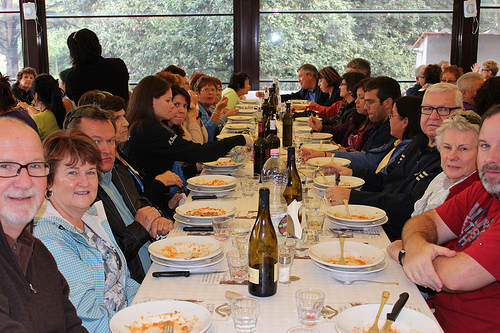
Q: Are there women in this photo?
A: Yes, there is a woman.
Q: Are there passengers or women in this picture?
A: Yes, there is a woman.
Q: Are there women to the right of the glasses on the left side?
A: Yes, there is a woman to the right of the glasses.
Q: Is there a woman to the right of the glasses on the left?
A: Yes, there is a woman to the right of the glasses.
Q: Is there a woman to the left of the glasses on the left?
A: No, the woman is to the right of the glasses.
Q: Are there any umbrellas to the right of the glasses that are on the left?
A: No, there is a woman to the right of the glasses.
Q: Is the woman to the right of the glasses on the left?
A: Yes, the woman is to the right of the glasses.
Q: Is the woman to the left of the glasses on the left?
A: No, the woman is to the right of the glasses.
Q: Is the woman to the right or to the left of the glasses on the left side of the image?
A: The woman is to the right of the glasses.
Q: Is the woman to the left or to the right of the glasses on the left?
A: The woman is to the right of the glasses.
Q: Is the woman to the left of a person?
A: Yes, the woman is to the left of a person.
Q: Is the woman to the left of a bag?
A: No, the woman is to the left of a person.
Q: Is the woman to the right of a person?
A: Yes, the woman is to the right of a person.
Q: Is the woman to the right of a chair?
A: No, the woman is to the right of a person.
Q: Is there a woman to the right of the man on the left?
A: Yes, there is a woman to the right of the man.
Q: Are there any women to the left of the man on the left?
A: No, the woman is to the right of the man.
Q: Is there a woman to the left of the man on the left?
A: No, the woman is to the right of the man.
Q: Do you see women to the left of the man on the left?
A: No, the woman is to the right of the man.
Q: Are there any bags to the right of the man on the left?
A: No, there is a woman to the right of the man.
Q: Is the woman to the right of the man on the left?
A: Yes, the woman is to the right of the man.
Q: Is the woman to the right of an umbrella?
A: No, the woman is to the right of the man.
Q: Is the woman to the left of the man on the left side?
A: No, the woman is to the right of the man.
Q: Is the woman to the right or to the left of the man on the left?
A: The woman is to the right of the man.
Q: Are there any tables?
A: Yes, there is a table.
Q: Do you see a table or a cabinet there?
A: Yes, there is a table.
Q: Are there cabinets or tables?
A: Yes, there is a table.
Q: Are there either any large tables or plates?
A: Yes, there is a large table.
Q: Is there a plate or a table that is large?
A: Yes, the table is large.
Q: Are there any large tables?
A: Yes, there is a large table.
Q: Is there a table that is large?
A: Yes, there is a table that is large.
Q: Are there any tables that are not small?
A: Yes, there is a large table.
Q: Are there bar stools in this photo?
A: No, there are no bar stools.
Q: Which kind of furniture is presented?
A: The furniture is a table.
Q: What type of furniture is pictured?
A: The furniture is a table.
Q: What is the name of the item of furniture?
A: The piece of furniture is a table.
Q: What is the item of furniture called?
A: The piece of furniture is a table.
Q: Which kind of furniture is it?
A: The piece of furniture is a table.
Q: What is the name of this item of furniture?
A: This is a table.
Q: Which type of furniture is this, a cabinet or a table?
A: This is a table.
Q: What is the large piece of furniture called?
A: The piece of furniture is a table.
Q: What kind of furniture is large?
A: The furniture is a table.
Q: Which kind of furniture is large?
A: The furniture is a table.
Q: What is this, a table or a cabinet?
A: This is a table.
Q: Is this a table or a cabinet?
A: This is a table.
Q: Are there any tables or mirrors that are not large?
A: No, there is a table but it is large.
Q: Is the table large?
A: Yes, the table is large.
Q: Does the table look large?
A: Yes, the table is large.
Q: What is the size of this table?
A: The table is large.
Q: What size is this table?
A: The table is large.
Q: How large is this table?
A: The table is large.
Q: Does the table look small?
A: No, the table is large.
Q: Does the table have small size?
A: No, the table is large.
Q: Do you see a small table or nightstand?
A: No, there is a table but it is large.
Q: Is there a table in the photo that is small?
A: No, there is a table but it is large.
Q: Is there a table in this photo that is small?
A: No, there is a table but it is large.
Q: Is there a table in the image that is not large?
A: No, there is a table but it is large.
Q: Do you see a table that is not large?
A: No, there is a table but it is large.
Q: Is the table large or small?
A: The table is large.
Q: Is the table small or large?
A: The table is large.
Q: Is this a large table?
A: Yes, this is a large table.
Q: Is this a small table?
A: No, this is a large table.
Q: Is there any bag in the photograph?
A: No, there are no bags.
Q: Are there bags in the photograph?
A: No, there are no bags.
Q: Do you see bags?
A: No, there are no bags.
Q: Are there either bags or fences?
A: No, there are no bags or fences.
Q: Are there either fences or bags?
A: No, there are no bags or fences.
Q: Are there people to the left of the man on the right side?
A: Yes, there is a person to the left of the man.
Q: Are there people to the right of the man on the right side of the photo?
A: No, the person is to the left of the man.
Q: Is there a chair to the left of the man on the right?
A: No, there is a person to the left of the man.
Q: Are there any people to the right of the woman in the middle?
A: Yes, there is a person to the right of the woman.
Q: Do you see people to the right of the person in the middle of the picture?
A: Yes, there is a person to the right of the woman.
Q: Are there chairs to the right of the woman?
A: No, there is a person to the right of the woman.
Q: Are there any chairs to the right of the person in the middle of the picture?
A: No, there is a person to the right of the woman.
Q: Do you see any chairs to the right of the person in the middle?
A: No, there is a person to the right of the woman.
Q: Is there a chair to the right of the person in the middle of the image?
A: No, there is a person to the right of the woman.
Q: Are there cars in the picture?
A: No, there are no cars.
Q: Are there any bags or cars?
A: No, there are no cars or bags.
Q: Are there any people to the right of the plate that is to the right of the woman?
A: Yes, there is a person to the right of the plate.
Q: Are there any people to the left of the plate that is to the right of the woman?
A: No, the person is to the right of the plate.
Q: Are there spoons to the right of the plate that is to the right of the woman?
A: No, there is a person to the right of the plate.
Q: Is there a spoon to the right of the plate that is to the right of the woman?
A: No, there is a person to the right of the plate.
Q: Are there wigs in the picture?
A: No, there are no wigs.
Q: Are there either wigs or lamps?
A: No, there are no wigs or lamps.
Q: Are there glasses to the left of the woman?
A: Yes, there are glasses to the left of the woman.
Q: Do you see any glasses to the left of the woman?
A: Yes, there are glasses to the left of the woman.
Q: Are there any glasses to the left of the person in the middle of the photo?
A: Yes, there are glasses to the left of the woman.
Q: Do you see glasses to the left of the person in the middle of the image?
A: Yes, there are glasses to the left of the woman.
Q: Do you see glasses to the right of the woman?
A: No, the glasses are to the left of the woman.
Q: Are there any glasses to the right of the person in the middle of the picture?
A: No, the glasses are to the left of the woman.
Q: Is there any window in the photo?
A: Yes, there are windows.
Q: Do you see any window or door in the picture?
A: Yes, there are windows.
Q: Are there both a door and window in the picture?
A: No, there are windows but no doors.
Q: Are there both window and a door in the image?
A: No, there are windows but no doors.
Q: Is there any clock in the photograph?
A: No, there are no clocks.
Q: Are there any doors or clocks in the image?
A: No, there are no clocks or doors.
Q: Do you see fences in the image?
A: No, there are no fences.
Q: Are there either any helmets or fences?
A: No, there are no fences or helmets.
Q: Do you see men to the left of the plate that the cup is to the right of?
A: Yes, there is a man to the left of the plate.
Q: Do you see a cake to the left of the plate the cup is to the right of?
A: No, there is a man to the left of the plate.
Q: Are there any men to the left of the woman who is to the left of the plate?
A: Yes, there is a man to the left of the woman.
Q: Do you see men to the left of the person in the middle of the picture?
A: Yes, there is a man to the left of the woman.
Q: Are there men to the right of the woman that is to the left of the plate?
A: No, the man is to the left of the woman.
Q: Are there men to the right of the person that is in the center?
A: No, the man is to the left of the woman.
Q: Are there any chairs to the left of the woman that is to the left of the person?
A: No, there is a man to the left of the woman.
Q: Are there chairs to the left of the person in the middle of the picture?
A: No, there is a man to the left of the woman.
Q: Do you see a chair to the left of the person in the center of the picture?
A: No, there is a man to the left of the woman.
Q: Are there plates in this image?
A: Yes, there is a plate.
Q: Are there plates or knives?
A: Yes, there is a plate.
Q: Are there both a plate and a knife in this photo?
A: Yes, there are both a plate and a knife.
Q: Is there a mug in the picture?
A: No, there are no mugs.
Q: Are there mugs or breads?
A: No, there are no mugs or breads.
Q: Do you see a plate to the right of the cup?
A: Yes, there is a plate to the right of the cup.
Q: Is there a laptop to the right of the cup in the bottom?
A: No, there is a plate to the right of the cup.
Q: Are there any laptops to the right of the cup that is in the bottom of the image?
A: No, there is a plate to the right of the cup.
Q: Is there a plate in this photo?
A: Yes, there is a plate.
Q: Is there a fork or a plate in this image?
A: Yes, there is a plate.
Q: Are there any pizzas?
A: No, there are no pizzas.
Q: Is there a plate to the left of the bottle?
A: Yes, there is a plate to the left of the bottle.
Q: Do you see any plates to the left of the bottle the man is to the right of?
A: Yes, there is a plate to the left of the bottle.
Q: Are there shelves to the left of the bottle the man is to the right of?
A: No, there is a plate to the left of the bottle.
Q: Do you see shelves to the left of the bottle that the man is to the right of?
A: No, there is a plate to the left of the bottle.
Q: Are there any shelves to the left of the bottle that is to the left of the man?
A: No, there is a plate to the left of the bottle.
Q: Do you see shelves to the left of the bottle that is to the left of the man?
A: No, there is a plate to the left of the bottle.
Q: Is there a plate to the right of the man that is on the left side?
A: Yes, there is a plate to the right of the man.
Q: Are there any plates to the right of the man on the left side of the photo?
A: Yes, there is a plate to the right of the man.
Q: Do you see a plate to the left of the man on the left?
A: No, the plate is to the right of the man.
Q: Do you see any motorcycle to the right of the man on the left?
A: No, there is a plate to the right of the man.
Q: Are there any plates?
A: Yes, there is a plate.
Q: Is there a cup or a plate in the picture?
A: Yes, there is a plate.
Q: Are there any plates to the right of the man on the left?
A: Yes, there is a plate to the right of the man.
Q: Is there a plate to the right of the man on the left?
A: Yes, there is a plate to the right of the man.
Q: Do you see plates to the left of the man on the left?
A: No, the plate is to the right of the man.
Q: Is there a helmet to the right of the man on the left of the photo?
A: No, there is a plate to the right of the man.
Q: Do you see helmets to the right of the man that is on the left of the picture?
A: No, there is a plate to the right of the man.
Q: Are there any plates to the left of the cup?
A: Yes, there is a plate to the left of the cup.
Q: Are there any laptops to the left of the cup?
A: No, there is a plate to the left of the cup.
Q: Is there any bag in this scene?
A: No, there are no bags.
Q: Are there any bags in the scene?
A: No, there are no bags.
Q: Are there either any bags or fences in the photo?
A: No, there are no bags or fences.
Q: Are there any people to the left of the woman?
A: Yes, there is a person to the left of the woman.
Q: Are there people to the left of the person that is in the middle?
A: Yes, there is a person to the left of the woman.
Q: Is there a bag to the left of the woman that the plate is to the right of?
A: No, there is a person to the left of the woman.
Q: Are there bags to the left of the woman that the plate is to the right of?
A: No, there is a person to the left of the woman.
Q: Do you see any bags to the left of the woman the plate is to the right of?
A: No, there is a person to the left of the woman.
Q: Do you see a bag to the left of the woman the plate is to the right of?
A: No, there is a person to the left of the woman.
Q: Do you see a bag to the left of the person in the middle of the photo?
A: No, there is a person to the left of the woman.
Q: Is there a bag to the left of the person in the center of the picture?
A: No, there is a person to the left of the woman.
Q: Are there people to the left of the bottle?
A: Yes, there is a person to the left of the bottle.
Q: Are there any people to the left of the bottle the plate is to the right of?
A: Yes, there is a person to the left of the bottle.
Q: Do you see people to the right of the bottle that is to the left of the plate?
A: No, the person is to the left of the bottle.